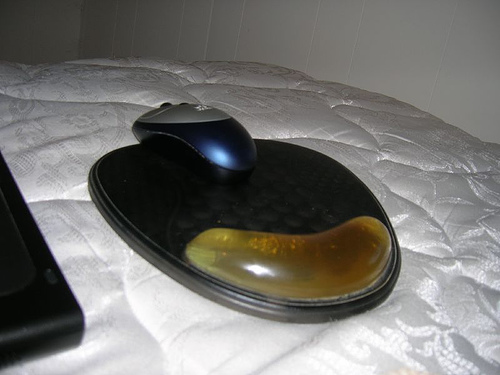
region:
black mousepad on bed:
[82, 86, 402, 322]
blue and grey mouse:
[131, 86, 250, 172]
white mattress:
[2, 43, 498, 373]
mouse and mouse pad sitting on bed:
[90, 95, 421, 319]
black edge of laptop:
[0, 154, 85, 361]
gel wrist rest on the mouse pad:
[188, 223, 393, 298]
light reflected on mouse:
[182, 133, 234, 165]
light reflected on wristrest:
[230, 244, 283, 289]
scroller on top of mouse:
[158, 96, 175, 110]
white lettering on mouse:
[196, 97, 213, 114]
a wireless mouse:
[138, 104, 255, 182]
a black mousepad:
[97, 177, 398, 324]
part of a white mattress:
[256, 61, 498, 144]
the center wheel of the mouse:
[160, 101, 169, 109]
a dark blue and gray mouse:
[133, 98, 253, 175]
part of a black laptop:
[1, 157, 82, 363]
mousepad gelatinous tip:
[186, 219, 398, 301]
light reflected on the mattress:
[134, 318, 356, 372]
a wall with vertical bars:
[153, 6, 497, 63]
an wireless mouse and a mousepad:
[101, 99, 405, 314]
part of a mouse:
[351, 280, 375, 297]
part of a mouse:
[230, 167, 246, 185]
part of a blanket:
[409, 226, 421, 251]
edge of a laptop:
[75, 305, 94, 330]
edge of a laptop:
[73, 293, 78, 305]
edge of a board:
[261, 202, 282, 214]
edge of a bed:
[212, 327, 242, 370]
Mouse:
[133, 93, 264, 177]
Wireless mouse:
[125, 93, 267, 177]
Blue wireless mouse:
[127, 91, 263, 178]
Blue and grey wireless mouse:
[127, 98, 265, 178]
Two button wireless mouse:
[125, 93, 263, 180]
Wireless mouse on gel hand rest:
[78, 99, 418, 321]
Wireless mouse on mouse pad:
[64, 91, 429, 330]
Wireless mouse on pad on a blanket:
[63, 90, 434, 336]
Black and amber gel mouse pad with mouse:
[89, 96, 421, 323]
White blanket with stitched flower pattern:
[400, 194, 498, 374]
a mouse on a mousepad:
[61, 18, 431, 374]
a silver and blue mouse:
[82, 19, 457, 346]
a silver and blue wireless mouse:
[73, 30, 431, 290]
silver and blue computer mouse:
[89, 66, 389, 244]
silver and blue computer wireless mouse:
[29, 52, 424, 364]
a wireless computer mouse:
[94, 78, 357, 368]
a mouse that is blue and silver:
[44, 14, 394, 336]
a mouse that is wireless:
[102, 51, 382, 327]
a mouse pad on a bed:
[26, 40, 458, 350]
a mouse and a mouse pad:
[87, 62, 389, 374]